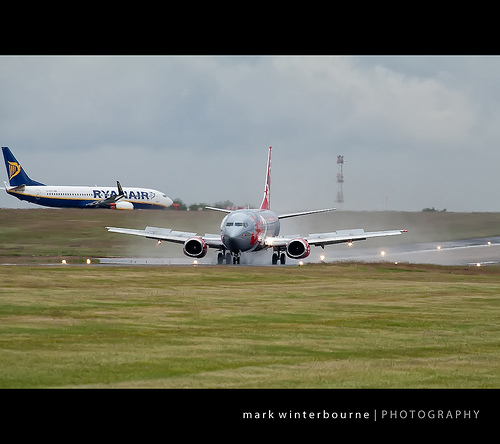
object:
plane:
[93, 138, 407, 266]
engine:
[284, 236, 311, 261]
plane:
[0, 142, 178, 211]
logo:
[5, 159, 23, 182]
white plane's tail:
[255, 144, 285, 211]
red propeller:
[288, 236, 307, 256]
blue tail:
[1, 139, 44, 186]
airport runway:
[331, 227, 497, 267]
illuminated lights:
[53, 250, 93, 265]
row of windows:
[45, 190, 95, 199]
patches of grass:
[396, 345, 494, 371]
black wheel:
[272, 253, 286, 263]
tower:
[327, 154, 353, 205]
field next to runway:
[0, 260, 499, 387]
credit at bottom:
[240, 408, 486, 419]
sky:
[0, 57, 496, 213]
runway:
[51, 236, 499, 268]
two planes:
[0, 145, 410, 263]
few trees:
[175, 197, 232, 214]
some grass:
[0, 260, 500, 385]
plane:
[0, 141, 194, 220]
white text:
[238, 408, 484, 422]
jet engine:
[180, 236, 213, 259]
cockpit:
[222, 221, 256, 227]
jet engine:
[113, 195, 135, 208]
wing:
[263, 227, 410, 249]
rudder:
[143, 221, 172, 237]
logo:
[240, 404, 483, 428]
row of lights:
[284, 239, 498, 258]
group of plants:
[169, 196, 259, 215]